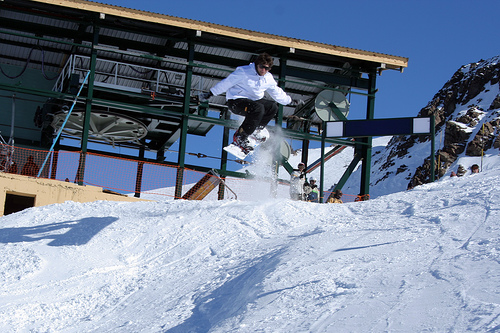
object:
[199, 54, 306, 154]
person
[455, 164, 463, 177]
people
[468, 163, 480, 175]
people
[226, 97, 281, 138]
pants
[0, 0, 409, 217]
building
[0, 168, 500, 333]
ground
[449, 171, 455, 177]
people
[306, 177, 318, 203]
people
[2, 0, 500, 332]
background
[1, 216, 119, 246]
shadow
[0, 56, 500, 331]
hill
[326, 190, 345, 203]
person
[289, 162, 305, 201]
person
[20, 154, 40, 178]
people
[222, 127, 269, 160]
snowboard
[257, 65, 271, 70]
goggles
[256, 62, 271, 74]
face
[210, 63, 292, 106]
white jacket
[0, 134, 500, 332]
snow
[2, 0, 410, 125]
roof